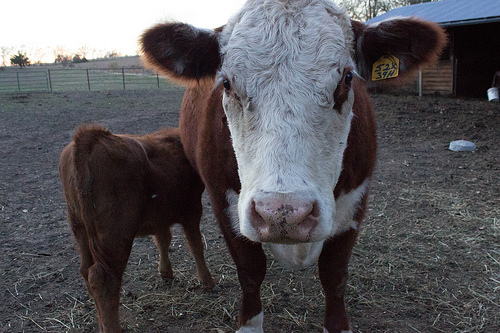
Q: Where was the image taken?
A: It was taken at the farm.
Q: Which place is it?
A: It is a farm.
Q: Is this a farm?
A: Yes, it is a farm.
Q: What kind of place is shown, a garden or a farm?
A: It is a farm.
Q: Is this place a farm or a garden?
A: It is a farm.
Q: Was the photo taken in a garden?
A: No, the picture was taken in a farm.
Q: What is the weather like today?
A: It is clear.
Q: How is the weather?
A: It is clear.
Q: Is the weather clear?
A: Yes, it is clear.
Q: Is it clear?
A: Yes, it is clear.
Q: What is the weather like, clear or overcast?
A: It is clear.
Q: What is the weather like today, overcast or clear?
A: It is clear.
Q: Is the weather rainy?
A: No, it is clear.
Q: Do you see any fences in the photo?
A: Yes, there is a fence.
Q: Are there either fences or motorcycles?
A: Yes, there is a fence.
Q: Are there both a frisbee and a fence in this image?
A: No, there is a fence but no frisbees.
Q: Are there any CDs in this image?
A: No, there are no cds.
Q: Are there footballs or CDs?
A: No, there are no CDs or footballs.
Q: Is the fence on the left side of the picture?
A: Yes, the fence is on the left of the image.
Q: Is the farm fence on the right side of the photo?
A: No, the fence is on the left of the image.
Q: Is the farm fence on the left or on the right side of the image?
A: The fence is on the left of the image.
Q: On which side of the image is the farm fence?
A: The fence is on the left of the image.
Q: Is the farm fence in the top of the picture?
A: Yes, the fence is in the top of the image.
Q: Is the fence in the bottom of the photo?
A: No, the fence is in the top of the image.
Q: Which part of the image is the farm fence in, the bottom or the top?
A: The fence is in the top of the image.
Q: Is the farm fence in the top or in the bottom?
A: The fence is in the top of the image.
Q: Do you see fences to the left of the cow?
A: Yes, there is a fence to the left of the cow.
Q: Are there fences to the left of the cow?
A: Yes, there is a fence to the left of the cow.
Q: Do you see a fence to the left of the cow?
A: Yes, there is a fence to the left of the cow.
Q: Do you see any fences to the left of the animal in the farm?
A: Yes, there is a fence to the left of the cow.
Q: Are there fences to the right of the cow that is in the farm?
A: No, the fence is to the left of the cow.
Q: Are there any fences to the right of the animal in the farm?
A: No, the fence is to the left of the cow.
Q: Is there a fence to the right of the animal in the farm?
A: No, the fence is to the left of the cow.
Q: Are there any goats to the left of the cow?
A: No, there is a fence to the left of the cow.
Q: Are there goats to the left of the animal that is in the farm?
A: No, there is a fence to the left of the cow.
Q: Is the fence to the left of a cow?
A: Yes, the fence is to the left of a cow.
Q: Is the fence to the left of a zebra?
A: No, the fence is to the left of a cow.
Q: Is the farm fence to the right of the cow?
A: No, the fence is to the left of the cow.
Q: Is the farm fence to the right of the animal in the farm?
A: No, the fence is to the left of the cow.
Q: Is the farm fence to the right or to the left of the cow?
A: The fence is to the left of the cow.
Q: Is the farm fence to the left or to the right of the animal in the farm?
A: The fence is to the left of the cow.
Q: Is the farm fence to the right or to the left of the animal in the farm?
A: The fence is to the left of the cow.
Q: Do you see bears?
A: No, there are no bears.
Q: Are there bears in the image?
A: No, there are no bears.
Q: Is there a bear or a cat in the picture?
A: No, there are no bears or cats.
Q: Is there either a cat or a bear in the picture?
A: No, there are no bears or cats.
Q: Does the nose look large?
A: Yes, the nose is large.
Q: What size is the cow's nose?
A: The nose is large.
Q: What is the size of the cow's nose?
A: The nose is large.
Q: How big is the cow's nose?
A: The nose is large.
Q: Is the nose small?
A: No, the nose is large.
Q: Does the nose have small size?
A: No, the nose is large.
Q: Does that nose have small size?
A: No, the nose is large.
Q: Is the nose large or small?
A: The nose is large.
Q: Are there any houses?
A: No, there are no houses.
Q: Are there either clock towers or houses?
A: No, there are no houses or clock towers.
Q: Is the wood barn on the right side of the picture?
A: Yes, the barn is on the right of the image.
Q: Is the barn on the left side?
A: No, the barn is on the right of the image.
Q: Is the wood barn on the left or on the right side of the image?
A: The barn is on the right of the image.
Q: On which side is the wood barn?
A: The barn is on the right of the image.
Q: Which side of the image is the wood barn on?
A: The barn is on the right of the image.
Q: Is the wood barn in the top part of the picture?
A: Yes, the barn is in the top of the image.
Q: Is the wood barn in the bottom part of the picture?
A: No, the barn is in the top of the image.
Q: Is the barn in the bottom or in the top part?
A: The barn is in the top of the image.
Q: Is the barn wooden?
A: Yes, the barn is wooden.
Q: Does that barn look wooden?
A: Yes, the barn is wooden.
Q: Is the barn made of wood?
A: Yes, the barn is made of wood.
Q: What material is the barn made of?
A: The barn is made of wood.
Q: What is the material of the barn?
A: The barn is made of wood.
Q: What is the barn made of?
A: The barn is made of wood.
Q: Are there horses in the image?
A: No, there are no horses.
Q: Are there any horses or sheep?
A: No, there are no horses or sheep.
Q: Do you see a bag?
A: No, there are no bags.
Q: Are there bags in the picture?
A: No, there are no bags.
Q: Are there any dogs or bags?
A: No, there are no bags or dogs.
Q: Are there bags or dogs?
A: No, there are no bags or dogs.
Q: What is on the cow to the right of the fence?
A: The tag is on the cow.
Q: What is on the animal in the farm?
A: The tag is on the cow.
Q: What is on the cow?
A: The tag is on the cow.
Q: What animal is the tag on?
A: The tag is on the cow.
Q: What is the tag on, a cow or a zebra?
A: The tag is on a cow.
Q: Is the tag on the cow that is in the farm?
A: Yes, the tag is on the cow.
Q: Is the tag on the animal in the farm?
A: Yes, the tag is on the cow.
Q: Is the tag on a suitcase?
A: No, the tag is on the cow.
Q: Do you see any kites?
A: No, there are no kites.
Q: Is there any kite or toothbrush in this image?
A: No, there are no kites or toothbrushes.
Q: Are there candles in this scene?
A: No, there are no candles.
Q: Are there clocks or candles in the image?
A: No, there are no candles or clocks.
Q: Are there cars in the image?
A: No, there are no cars.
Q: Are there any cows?
A: Yes, there is a cow.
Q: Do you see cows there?
A: Yes, there is a cow.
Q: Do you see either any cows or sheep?
A: Yes, there is a cow.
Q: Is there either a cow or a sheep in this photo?
A: Yes, there is a cow.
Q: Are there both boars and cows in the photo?
A: No, there is a cow but no boars.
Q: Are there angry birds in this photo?
A: No, there are no angry birds.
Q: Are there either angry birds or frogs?
A: No, there are no angry birds or frogs.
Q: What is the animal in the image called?
A: The animal is a cow.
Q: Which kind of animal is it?
A: The animal is a cow.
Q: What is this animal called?
A: This is a cow.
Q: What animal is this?
A: This is a cow.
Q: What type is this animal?
A: This is a cow.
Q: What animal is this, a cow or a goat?
A: This is a cow.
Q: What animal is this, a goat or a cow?
A: This is a cow.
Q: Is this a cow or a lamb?
A: This is a cow.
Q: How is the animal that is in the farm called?
A: The animal is a cow.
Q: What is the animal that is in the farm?
A: The animal is a cow.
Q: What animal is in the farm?
A: The animal is a cow.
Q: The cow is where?
A: The cow is in the farm.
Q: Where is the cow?
A: The cow is in the farm.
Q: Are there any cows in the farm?
A: Yes, there is a cow in the farm.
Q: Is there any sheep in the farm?
A: No, there is a cow in the farm.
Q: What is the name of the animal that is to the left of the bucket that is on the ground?
A: The animal is a cow.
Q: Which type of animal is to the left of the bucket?
A: The animal is a cow.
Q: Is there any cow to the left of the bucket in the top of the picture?
A: Yes, there is a cow to the left of the bucket.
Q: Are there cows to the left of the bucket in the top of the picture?
A: Yes, there is a cow to the left of the bucket.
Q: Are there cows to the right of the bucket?
A: No, the cow is to the left of the bucket.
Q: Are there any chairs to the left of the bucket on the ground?
A: No, there is a cow to the left of the bucket.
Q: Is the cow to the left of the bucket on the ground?
A: Yes, the cow is to the left of the bucket.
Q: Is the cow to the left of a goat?
A: No, the cow is to the left of the bucket.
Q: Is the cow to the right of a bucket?
A: No, the cow is to the left of a bucket.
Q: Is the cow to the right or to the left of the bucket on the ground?
A: The cow is to the left of the bucket.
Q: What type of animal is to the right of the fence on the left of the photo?
A: The animal is a cow.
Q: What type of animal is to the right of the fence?
A: The animal is a cow.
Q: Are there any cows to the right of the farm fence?
A: Yes, there is a cow to the right of the fence.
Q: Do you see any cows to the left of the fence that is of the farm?
A: No, the cow is to the right of the fence.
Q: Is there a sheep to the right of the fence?
A: No, there is a cow to the right of the fence.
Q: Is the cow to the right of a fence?
A: Yes, the cow is to the right of a fence.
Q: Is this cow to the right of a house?
A: No, the cow is to the right of a fence.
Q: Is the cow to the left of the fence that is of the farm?
A: No, the cow is to the right of the fence.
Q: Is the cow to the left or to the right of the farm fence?
A: The cow is to the right of the fence.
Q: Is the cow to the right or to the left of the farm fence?
A: The cow is to the right of the fence.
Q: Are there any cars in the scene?
A: No, there are no cars.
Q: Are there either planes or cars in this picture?
A: No, there are no cars or planes.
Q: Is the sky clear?
A: Yes, the sky is clear.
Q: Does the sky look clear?
A: Yes, the sky is clear.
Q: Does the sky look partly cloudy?
A: No, the sky is clear.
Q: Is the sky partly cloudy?
A: No, the sky is clear.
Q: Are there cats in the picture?
A: No, there are no cats.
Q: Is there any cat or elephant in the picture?
A: No, there are no cats or elephants.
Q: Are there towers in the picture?
A: No, there are no towers.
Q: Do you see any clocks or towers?
A: No, there are no towers or clocks.